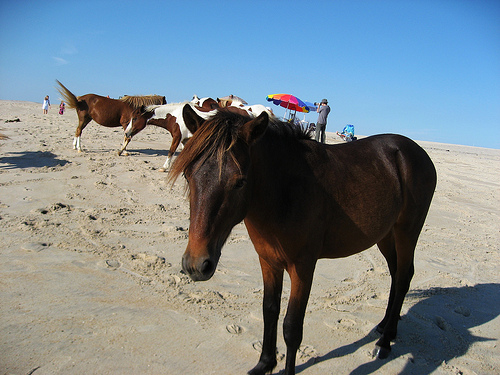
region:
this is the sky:
[173, 22, 337, 74]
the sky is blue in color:
[236, 28, 380, 65]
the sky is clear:
[313, 15, 448, 62]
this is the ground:
[18, 270, 82, 341]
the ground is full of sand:
[43, 239, 147, 342]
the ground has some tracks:
[37, 200, 155, 255]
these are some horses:
[87, 94, 418, 362]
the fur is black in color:
[302, 155, 405, 212]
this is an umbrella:
[263, 90, 304, 109]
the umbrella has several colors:
[276, 95, 297, 107]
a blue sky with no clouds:
[5, 5, 492, 127]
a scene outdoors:
[6, 5, 496, 310]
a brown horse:
[165, 95, 435, 370]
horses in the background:
[35, 47, 295, 168]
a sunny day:
[10, 0, 497, 366]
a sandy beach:
[0, 105, 490, 370]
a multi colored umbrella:
[255, 80, 322, 141]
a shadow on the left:
[5, 130, 82, 177]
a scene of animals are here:
[0, 0, 495, 360]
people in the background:
[26, 82, 93, 129]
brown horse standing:
[156, 118, 447, 300]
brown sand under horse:
[100, 280, 213, 333]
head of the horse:
[158, 161, 249, 286]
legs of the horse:
[243, 247, 455, 352]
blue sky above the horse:
[352, 16, 474, 68]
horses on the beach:
[67, 43, 376, 279]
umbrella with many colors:
[265, 81, 310, 128]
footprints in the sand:
[33, 181, 128, 277]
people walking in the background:
[35, 89, 70, 124]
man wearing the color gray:
[310, 95, 343, 142]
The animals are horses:
[56, 69, 446, 374]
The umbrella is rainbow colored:
[266, 92, 309, 126]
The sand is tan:
[2, 100, 497, 374]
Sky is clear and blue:
[0, 0, 499, 150]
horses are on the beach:
[1, 78, 445, 373]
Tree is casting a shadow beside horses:
[0, 146, 70, 171]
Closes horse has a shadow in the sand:
[248, 279, 499, 374]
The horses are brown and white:
[53, 76, 437, 372]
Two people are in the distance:
[38, 90, 70, 122]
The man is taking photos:
[308, 94, 335, 149]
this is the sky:
[101, 7, 314, 52]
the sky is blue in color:
[208, 8, 383, 35]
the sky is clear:
[385, 17, 453, 93]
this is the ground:
[20, 196, 98, 347]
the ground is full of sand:
[15, 271, 101, 358]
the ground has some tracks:
[38, 207, 176, 286]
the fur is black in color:
[393, 145, 414, 172]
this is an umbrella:
[273, 94, 296, 111]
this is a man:
[314, 99, 326, 139]